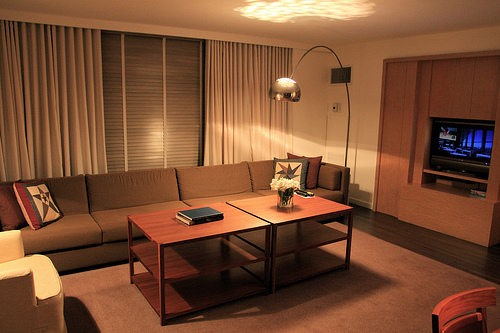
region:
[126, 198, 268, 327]
Brown table in living room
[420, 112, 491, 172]
Television in living room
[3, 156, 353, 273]
Long brown couch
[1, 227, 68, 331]
Yellow chair in living room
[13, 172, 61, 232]
Pillow with star design on couch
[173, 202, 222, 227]
Two books on brown table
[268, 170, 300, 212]
White flowers in pot on table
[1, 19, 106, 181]
Beige curtains in living room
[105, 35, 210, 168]
Blinds on living room window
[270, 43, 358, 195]
Goose neck lamp in living room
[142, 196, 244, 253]
book is blue on table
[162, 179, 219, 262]
book is blue on table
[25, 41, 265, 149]
The curtains around the windows.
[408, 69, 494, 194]
A built in television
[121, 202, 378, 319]
Wooden coffee table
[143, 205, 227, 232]
Book sitting on top of table.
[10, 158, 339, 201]
Long brown couch.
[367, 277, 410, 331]
Brown carpet flooring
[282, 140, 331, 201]
Two pillows laying on couch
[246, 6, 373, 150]
Large floor lamp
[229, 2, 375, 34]
Light reflection on the ceiling.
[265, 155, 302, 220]
White flowers in a vase.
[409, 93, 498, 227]
the TV is turned on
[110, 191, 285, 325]
a book is on the table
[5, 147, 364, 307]
pillows are on the sofa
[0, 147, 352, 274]
the sofa is brown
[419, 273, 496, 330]
the chair is wooden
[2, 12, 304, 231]
curtains are covering the window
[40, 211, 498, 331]
the area rug is brown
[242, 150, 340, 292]
flowers are on the table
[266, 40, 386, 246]
the floor lamp is lit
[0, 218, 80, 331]
the chair is cream colored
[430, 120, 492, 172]
tv inside entertainment center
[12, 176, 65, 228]
star throw pillow with red trim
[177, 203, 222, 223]
black book on coffee table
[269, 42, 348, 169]
silver curved lamp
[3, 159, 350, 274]
long brown modern couch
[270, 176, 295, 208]
white flowers in clear vase on the coffee table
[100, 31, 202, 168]
blinds between two curtains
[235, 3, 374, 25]
light fixture on the ceiling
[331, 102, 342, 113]
thermostat on the wall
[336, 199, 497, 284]
section of wood flooring